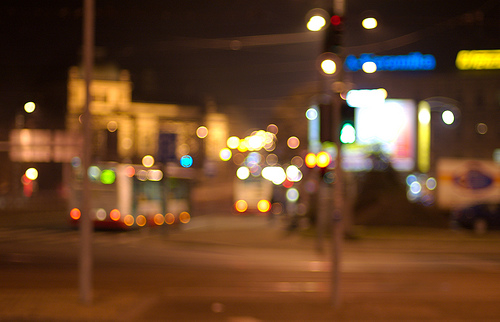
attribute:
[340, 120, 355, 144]
light — green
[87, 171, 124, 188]
light — green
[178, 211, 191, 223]
light — blurry, small, orange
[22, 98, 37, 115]
light — shining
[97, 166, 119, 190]
light — green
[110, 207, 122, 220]
light — blurry, orange, small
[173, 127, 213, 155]
light — traffic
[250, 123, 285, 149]
light — traffic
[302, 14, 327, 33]
light — bright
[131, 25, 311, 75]
lines — power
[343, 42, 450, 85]
sign — blue, light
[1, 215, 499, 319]
road — clear, dry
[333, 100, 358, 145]
sign — walk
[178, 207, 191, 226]
light — small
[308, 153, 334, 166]
light — small, blurry, orange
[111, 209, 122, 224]
light — orange, small, blurry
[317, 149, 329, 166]
light — bright, small, yellow